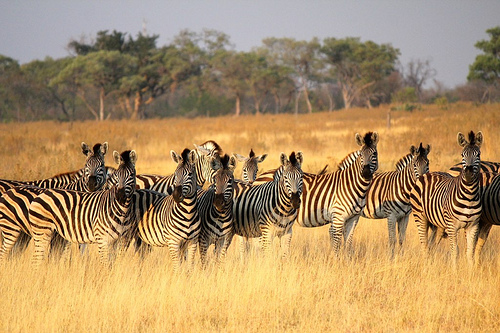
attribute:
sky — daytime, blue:
[0, 1, 469, 87]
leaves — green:
[0, 30, 428, 128]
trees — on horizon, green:
[1, 30, 461, 132]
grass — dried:
[75, 260, 416, 328]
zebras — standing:
[0, 124, 481, 260]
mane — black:
[333, 144, 368, 174]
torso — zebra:
[293, 158, 342, 226]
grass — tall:
[0, 108, 476, 329]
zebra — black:
[307, 136, 387, 254]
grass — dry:
[115, 270, 442, 326]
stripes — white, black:
[38, 196, 84, 228]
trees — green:
[41, 33, 398, 89]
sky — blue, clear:
[250, 3, 487, 40]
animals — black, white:
[27, 143, 465, 237]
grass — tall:
[169, 285, 252, 308]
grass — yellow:
[200, 280, 313, 302]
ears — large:
[451, 129, 488, 149]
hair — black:
[285, 150, 304, 161]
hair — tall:
[335, 151, 361, 172]